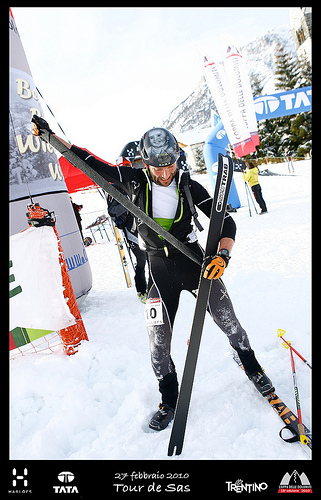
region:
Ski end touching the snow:
[171, 437, 179, 455]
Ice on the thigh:
[222, 316, 231, 322]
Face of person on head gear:
[149, 129, 164, 142]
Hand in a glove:
[206, 257, 223, 276]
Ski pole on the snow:
[294, 374, 296, 384]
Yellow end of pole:
[277, 329, 283, 335]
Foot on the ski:
[257, 379, 271, 391]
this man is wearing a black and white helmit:
[136, 125, 180, 168]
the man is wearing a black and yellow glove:
[198, 246, 233, 279]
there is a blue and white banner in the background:
[250, 90, 317, 122]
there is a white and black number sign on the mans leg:
[142, 291, 166, 325]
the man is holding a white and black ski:
[189, 152, 237, 352]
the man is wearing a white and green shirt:
[143, 174, 187, 227]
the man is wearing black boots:
[142, 374, 180, 436]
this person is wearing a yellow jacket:
[245, 165, 261, 187]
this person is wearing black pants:
[248, 184, 268, 215]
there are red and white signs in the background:
[212, 55, 249, 162]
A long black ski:
[166, 153, 235, 456]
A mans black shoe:
[142, 372, 181, 434]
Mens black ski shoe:
[240, 346, 280, 401]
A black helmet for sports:
[138, 125, 184, 170]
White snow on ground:
[30, 358, 134, 451]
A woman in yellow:
[244, 155, 269, 218]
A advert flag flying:
[198, 39, 269, 156]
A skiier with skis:
[27, 105, 309, 446]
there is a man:
[29, 113, 281, 433]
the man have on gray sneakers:
[146, 369, 279, 431]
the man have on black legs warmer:
[156, 344, 265, 408]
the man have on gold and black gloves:
[28, 108, 228, 284]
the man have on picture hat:
[139, 124, 187, 168]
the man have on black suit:
[66, 140, 248, 408]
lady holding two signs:
[200, 46, 267, 217]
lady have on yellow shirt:
[242, 166, 262, 185]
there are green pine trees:
[188, 38, 310, 181]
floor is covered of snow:
[60, 367, 150, 469]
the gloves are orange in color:
[200, 247, 237, 282]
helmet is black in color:
[121, 117, 195, 168]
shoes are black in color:
[143, 398, 176, 427]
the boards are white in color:
[205, 67, 262, 174]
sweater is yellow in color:
[249, 160, 260, 189]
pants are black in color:
[250, 186, 273, 213]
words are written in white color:
[21, 128, 68, 193]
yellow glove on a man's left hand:
[202, 253, 228, 280]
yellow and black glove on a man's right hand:
[28, 114, 55, 142]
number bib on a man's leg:
[143, 295, 165, 326]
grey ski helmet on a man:
[139, 127, 181, 168]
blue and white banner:
[240, 84, 314, 123]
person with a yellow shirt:
[242, 159, 269, 217]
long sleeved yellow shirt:
[243, 166, 259, 187]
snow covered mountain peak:
[120, 20, 307, 152]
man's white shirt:
[146, 178, 183, 223]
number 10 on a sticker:
[144, 306, 157, 322]